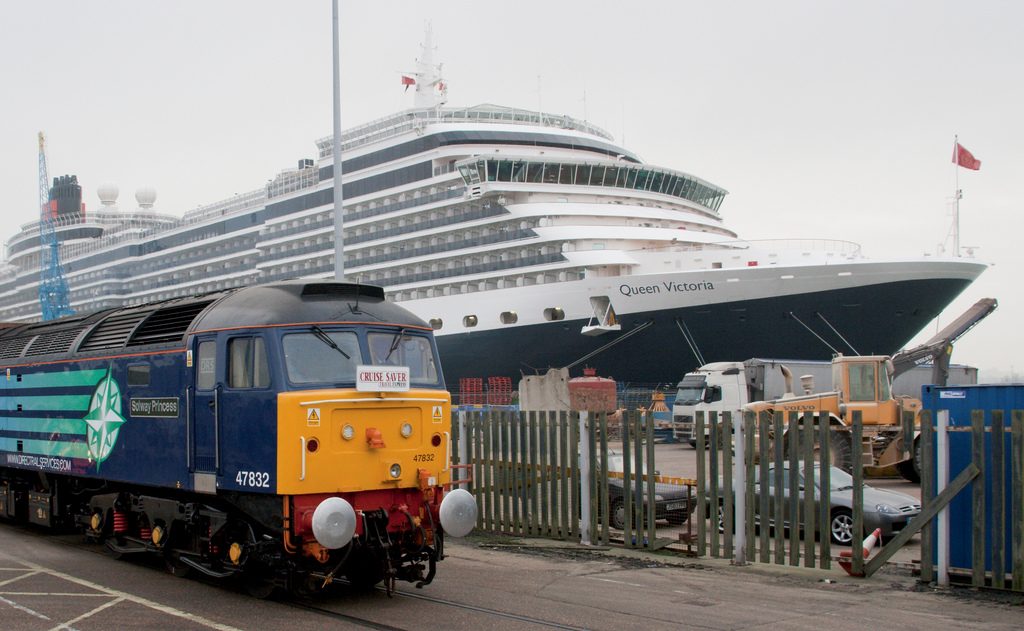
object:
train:
[0, 278, 477, 608]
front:
[274, 278, 477, 605]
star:
[82, 359, 129, 474]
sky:
[2, 0, 1024, 381]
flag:
[952, 135, 982, 170]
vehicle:
[670, 357, 979, 449]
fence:
[451, 408, 1021, 607]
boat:
[0, 25, 988, 407]